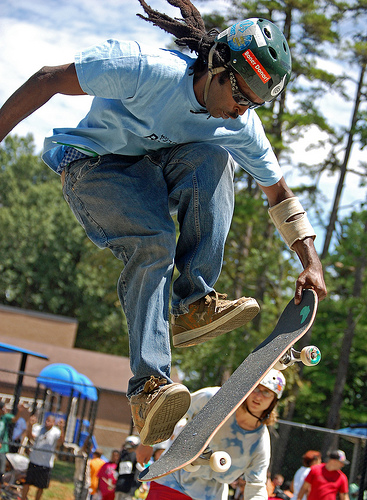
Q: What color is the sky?
A: Blue.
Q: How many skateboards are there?
A: One.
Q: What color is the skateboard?
A: Black.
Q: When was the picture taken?
A: Daytime.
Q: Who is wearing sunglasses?
A: The closest man.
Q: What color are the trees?
A: Green.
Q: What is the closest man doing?
A: Skateboarding.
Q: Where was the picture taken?
A: At a skate park.